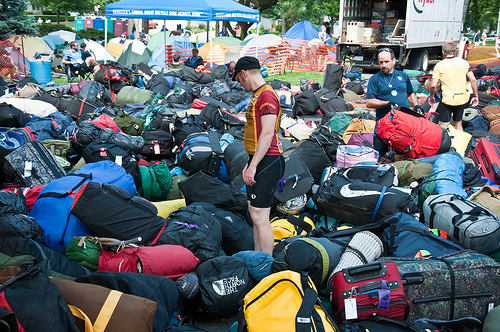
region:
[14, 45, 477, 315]
luggage covering the ground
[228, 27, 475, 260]
three men standing in luggage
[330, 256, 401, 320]
red suitcase with black handle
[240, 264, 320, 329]
yellow bag with black strap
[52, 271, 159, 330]
brown bag with yellow strap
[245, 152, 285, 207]
black shorts of man standing in luggage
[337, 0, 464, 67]
white box truck with back open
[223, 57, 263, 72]
black hat of man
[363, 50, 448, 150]
man carrying red bag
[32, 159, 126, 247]
two blue bags together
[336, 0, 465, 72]
large white box truck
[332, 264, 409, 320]
red suit case with black handle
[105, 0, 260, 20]
blue pop up tent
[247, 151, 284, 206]
black exercise shorts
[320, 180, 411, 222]
Nike bag is full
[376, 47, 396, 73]
sunglasses on the man's head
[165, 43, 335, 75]
orange boundary fence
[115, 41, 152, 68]
green and white tent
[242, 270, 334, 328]
large yellow duffel bag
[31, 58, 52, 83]
large blue bucket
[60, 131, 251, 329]
These are a lot of bags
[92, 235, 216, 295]
The bag is red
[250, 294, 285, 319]
The bag is yellow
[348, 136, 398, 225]
The bag is nike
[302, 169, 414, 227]
The bag is navy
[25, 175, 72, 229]
The bag is blue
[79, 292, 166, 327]
The bag is brown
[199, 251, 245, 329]
This is the north face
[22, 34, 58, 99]
This is a cooler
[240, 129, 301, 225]
These are shorts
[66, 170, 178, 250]
This is a bag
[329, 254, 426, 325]
This is a bag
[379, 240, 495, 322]
This is a bag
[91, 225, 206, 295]
This is a bag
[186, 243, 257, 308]
This is a bag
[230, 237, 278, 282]
This is a bag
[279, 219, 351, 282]
This is a bag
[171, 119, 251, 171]
This is a bag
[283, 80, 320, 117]
This is a bag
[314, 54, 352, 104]
This is a bag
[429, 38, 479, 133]
The person is wearing a yellow shirt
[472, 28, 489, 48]
The two people are walking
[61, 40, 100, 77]
The person is sitting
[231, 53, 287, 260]
The man is wearing a black hat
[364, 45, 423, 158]
The man has sunglasses on his head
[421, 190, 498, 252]
A large grey duffel bag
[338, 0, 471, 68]
A large white box truck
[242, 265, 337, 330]
The duffel bag is bright yellow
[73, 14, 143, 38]
A row of port a potties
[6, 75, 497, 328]
A mountain of suitcases and duffel bags